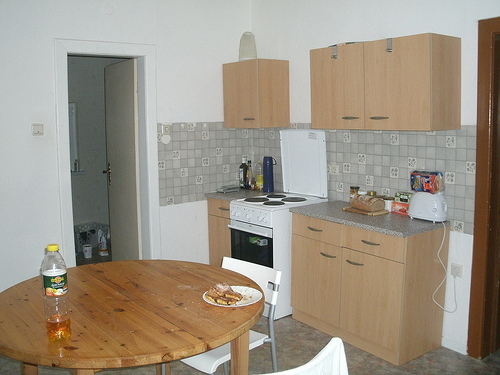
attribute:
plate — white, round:
[206, 276, 264, 315]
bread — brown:
[348, 192, 385, 210]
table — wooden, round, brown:
[15, 256, 261, 371]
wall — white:
[10, 22, 59, 240]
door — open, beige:
[97, 63, 145, 257]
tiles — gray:
[158, 126, 226, 188]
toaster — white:
[407, 191, 453, 223]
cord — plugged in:
[435, 228, 463, 313]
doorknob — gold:
[102, 161, 114, 194]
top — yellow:
[39, 240, 67, 253]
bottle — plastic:
[37, 240, 79, 339]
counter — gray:
[345, 215, 424, 239]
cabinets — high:
[310, 31, 461, 133]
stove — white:
[228, 190, 295, 258]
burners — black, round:
[242, 188, 308, 207]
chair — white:
[200, 251, 303, 373]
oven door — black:
[228, 223, 280, 268]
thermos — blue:
[256, 155, 280, 194]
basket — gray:
[76, 224, 114, 246]